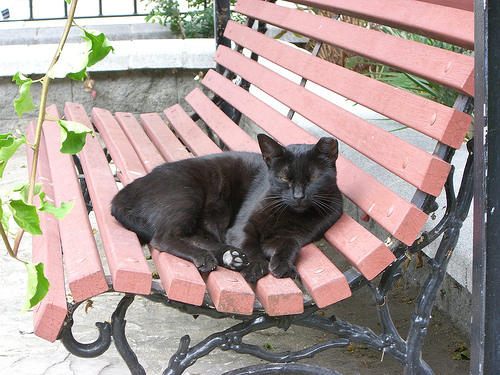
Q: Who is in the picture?
A: Cat.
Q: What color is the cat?
A: Black.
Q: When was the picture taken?
A: In the daytime.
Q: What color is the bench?
A: Red.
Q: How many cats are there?
A: 1.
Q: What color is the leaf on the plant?
A: Green.